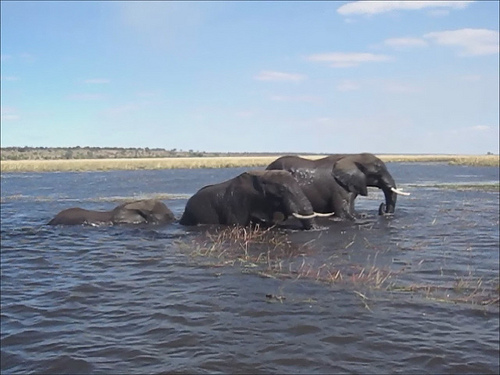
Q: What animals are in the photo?
A: Elephants.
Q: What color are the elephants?
A: Grey.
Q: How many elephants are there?
A: Three.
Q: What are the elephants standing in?
A: Water.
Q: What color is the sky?
A: Blue.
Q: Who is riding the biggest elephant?
A: No one.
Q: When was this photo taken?
A: Daytime.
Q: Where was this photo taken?
A: Water.